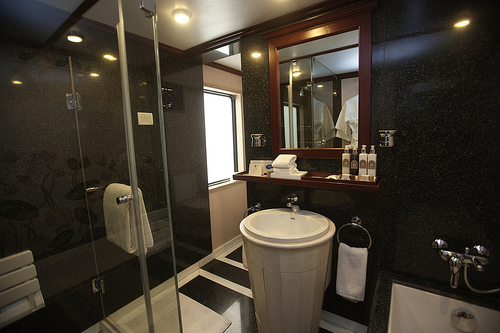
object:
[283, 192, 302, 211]
faucet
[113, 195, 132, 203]
towel hanging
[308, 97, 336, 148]
reflection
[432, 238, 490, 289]
faucet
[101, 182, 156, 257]
towel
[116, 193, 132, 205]
door handle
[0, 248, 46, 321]
seat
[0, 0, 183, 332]
shower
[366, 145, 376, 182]
toiletries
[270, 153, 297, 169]
towels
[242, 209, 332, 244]
sink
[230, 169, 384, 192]
shelf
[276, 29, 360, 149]
mirror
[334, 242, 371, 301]
towel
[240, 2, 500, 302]
wall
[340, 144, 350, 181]
bottle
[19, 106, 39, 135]
material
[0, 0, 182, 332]
door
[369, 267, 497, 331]
bathtub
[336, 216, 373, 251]
holder